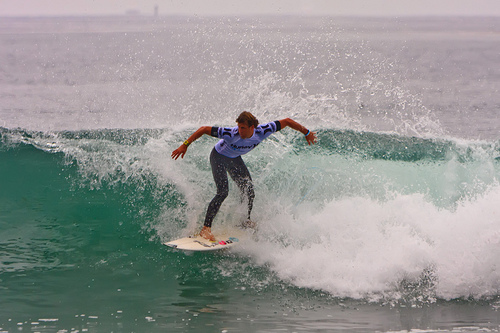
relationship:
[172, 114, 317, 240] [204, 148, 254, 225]
person wearing pants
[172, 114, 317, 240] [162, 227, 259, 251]
person using surfboard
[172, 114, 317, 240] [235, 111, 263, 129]
person has hair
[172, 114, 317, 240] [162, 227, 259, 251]
person riding surfboard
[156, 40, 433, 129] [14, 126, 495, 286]
spray above wave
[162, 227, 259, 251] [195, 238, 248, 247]
surfboard has decals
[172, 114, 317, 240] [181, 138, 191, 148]
person wearing wristband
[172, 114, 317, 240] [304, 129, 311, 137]
person wearing bracelet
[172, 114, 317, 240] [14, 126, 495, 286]
person riding wave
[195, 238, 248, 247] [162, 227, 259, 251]
decals are on surfboard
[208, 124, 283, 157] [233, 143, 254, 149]
shirt has name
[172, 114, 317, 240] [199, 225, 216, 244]
person has foot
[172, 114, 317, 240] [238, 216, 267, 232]
person has foot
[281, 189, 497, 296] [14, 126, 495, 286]
foam on wave